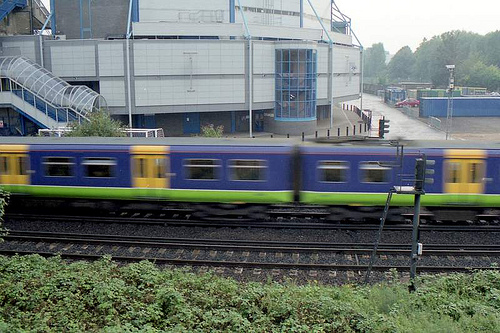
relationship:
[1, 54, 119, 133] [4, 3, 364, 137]
staircase beside building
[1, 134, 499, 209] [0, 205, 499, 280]
train on tracks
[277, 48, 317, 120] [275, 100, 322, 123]
window with frames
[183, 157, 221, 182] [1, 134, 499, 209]
window on train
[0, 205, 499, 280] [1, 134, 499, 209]
tracks of train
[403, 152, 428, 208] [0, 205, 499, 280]
stoplight near tracks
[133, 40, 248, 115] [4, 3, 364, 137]
wall of building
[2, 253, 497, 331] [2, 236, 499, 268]
shrub near track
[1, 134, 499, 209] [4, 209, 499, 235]
train on track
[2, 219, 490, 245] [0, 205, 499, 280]
gravel between tracks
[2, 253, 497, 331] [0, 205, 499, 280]
vegetation alongside tracks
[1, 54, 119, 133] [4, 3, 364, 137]
stairway on building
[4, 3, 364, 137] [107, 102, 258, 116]
building has trim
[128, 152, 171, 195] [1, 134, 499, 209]
doors of train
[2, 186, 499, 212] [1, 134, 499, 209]
border on train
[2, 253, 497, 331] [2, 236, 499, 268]
shrubs beside track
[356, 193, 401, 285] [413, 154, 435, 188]
ladder on stoplight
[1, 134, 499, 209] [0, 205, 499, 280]
train riding tracks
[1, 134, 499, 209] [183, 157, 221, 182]
train has window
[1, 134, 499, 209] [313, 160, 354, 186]
train has window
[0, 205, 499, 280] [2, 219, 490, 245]
tracks have gravel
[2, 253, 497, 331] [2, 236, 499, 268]
bushes beside track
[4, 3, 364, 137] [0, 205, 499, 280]
station beside tracks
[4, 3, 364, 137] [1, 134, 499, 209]
station of train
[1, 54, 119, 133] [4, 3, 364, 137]
staircase to station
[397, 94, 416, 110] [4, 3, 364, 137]
car front building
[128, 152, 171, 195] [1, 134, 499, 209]
door of train